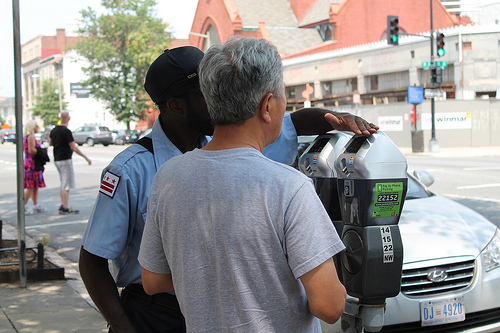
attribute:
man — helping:
[80, 44, 379, 330]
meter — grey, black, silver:
[298, 126, 408, 332]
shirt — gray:
[137, 146, 349, 331]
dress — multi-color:
[21, 135, 46, 190]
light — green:
[391, 34, 397, 43]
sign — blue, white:
[406, 85, 425, 104]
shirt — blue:
[80, 111, 300, 296]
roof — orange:
[224, 0, 331, 58]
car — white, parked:
[299, 140, 500, 332]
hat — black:
[146, 45, 206, 103]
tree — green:
[73, 0, 175, 131]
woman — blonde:
[22, 121, 51, 216]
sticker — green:
[371, 180, 404, 216]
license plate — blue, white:
[420, 293, 469, 327]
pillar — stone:
[411, 129, 426, 153]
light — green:
[437, 47, 446, 58]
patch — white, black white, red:
[99, 169, 122, 198]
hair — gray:
[196, 37, 283, 126]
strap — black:
[136, 136, 154, 156]